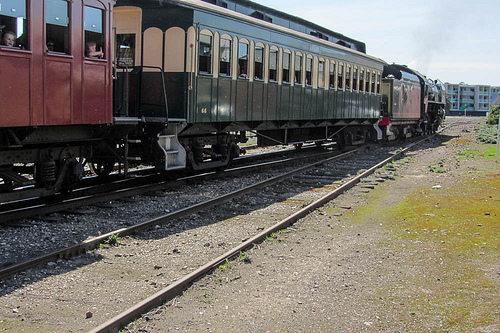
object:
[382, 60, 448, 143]
engine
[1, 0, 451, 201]
train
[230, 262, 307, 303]
ground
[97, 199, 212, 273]
tracks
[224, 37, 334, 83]
windows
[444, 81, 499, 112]
building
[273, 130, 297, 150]
feet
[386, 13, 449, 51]
sky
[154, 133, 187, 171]
stairs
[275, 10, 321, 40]
rails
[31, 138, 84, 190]
wheels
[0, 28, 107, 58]
kids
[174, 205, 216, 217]
gravel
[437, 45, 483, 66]
clouds